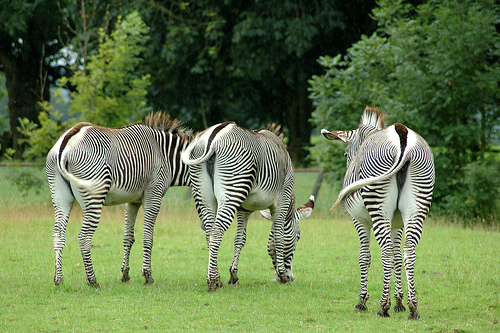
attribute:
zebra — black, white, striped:
[178, 121, 300, 292]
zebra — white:
[185, 125, 322, 288]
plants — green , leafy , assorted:
[0, 15, 483, 215]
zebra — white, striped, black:
[182, 114, 317, 288]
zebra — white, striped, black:
[44, 114, 209, 285]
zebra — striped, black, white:
[318, 109, 436, 317]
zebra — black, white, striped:
[180, 120, 309, 300]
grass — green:
[256, 280, 322, 307]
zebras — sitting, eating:
[40, 98, 439, 323]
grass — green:
[133, 276, 311, 331]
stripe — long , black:
[389, 117, 421, 158]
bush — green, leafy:
[431, 128, 499, 224]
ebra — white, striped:
[32, 100, 459, 317]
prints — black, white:
[81, 133, 127, 173]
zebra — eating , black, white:
[30, 110, 198, 304]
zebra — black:
[45, 108, 193, 289]